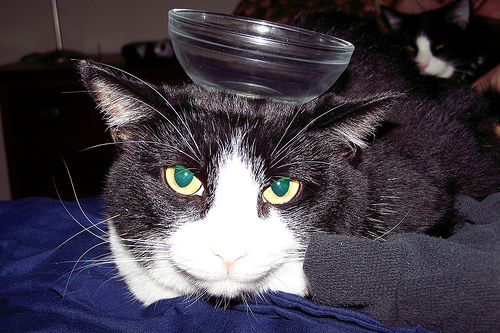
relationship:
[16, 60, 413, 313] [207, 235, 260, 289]
cat has nose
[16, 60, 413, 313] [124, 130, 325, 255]
cat has face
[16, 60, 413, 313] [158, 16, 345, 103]
cat with bowl